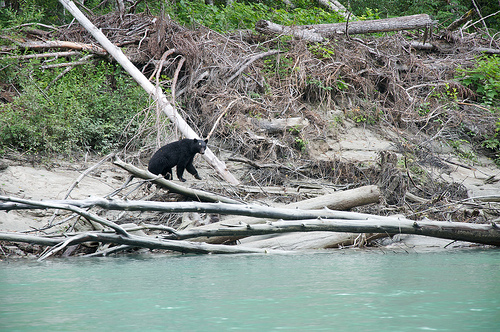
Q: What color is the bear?
A: Black.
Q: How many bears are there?
A: One.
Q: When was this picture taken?
A: During the day.